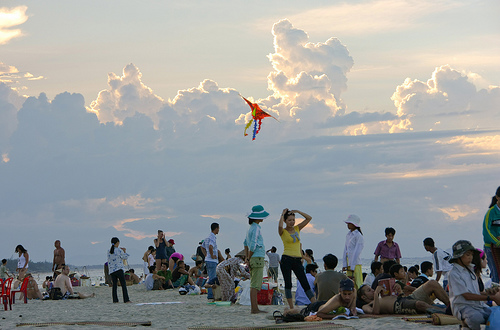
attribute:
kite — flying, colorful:
[235, 89, 276, 147]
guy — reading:
[356, 275, 437, 327]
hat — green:
[246, 200, 271, 221]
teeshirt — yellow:
[277, 220, 307, 267]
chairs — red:
[1, 270, 39, 316]